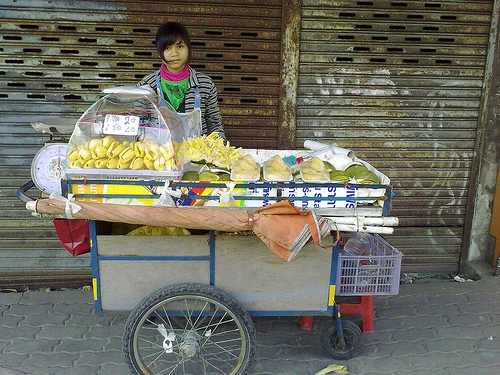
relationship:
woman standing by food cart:
[144, 20, 227, 141] [18, 88, 402, 374]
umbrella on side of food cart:
[25, 200, 400, 263] [18, 88, 402, 374]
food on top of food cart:
[64, 130, 382, 186] [18, 88, 402, 374]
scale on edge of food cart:
[30, 141, 73, 200] [18, 88, 402, 374]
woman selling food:
[144, 20, 227, 141] [64, 130, 382, 186]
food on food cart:
[64, 130, 382, 186] [18, 88, 402, 374]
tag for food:
[103, 114, 141, 136] [64, 130, 382, 186]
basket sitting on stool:
[341, 237, 401, 296] [300, 275, 373, 332]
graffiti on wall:
[401, 84, 471, 259] [0, 0, 474, 271]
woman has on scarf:
[144, 20, 227, 141] [160, 63, 193, 111]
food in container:
[69, 135, 176, 171] [67, 86, 185, 175]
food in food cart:
[64, 130, 382, 186] [18, 88, 402, 374]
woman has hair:
[144, 20, 227, 141] [155, 21, 189, 63]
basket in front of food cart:
[341, 237, 401, 296] [18, 88, 402, 374]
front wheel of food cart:
[322, 320, 363, 360] [18, 88, 402, 374]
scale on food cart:
[30, 141, 73, 200] [18, 88, 402, 374]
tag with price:
[103, 114, 141, 136] [106, 115, 135, 126]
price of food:
[106, 115, 135, 126] [69, 135, 176, 171]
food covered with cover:
[69, 135, 176, 171] [67, 86, 185, 175]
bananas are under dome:
[69, 135, 176, 171] [67, 86, 185, 175]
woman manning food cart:
[144, 20, 227, 141] [18, 88, 402, 374]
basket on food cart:
[341, 237, 401, 296] [18, 88, 402, 374]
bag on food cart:
[53, 217, 91, 256] [18, 88, 402, 374]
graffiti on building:
[401, 84, 471, 259] [4, 7, 500, 276]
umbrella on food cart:
[25, 200, 400, 263] [18, 88, 402, 374]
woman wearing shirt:
[144, 20, 227, 141] [140, 70, 226, 140]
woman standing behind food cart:
[144, 20, 227, 141] [18, 88, 402, 374]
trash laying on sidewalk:
[307, 359, 356, 374] [4, 282, 499, 374]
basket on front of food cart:
[341, 237, 401, 296] [18, 88, 402, 374]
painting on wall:
[302, 70, 472, 250] [0, 0, 474, 271]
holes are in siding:
[2, 21, 261, 110] [0, 4, 288, 205]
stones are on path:
[410, 316, 459, 351] [4, 282, 499, 374]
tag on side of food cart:
[103, 114, 141, 136] [18, 88, 402, 374]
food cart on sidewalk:
[18, 88, 402, 374] [4, 282, 499, 374]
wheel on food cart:
[126, 281, 259, 373] [18, 88, 402, 374]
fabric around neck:
[160, 65, 191, 81] [165, 65, 190, 81]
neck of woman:
[165, 65, 190, 81] [144, 20, 227, 141]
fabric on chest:
[163, 79, 187, 108] [154, 79, 201, 109]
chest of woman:
[154, 79, 201, 109] [144, 20, 227, 141]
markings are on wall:
[302, 70, 472, 250] [0, 0, 474, 271]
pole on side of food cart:
[328, 213, 401, 236] [18, 88, 402, 374]